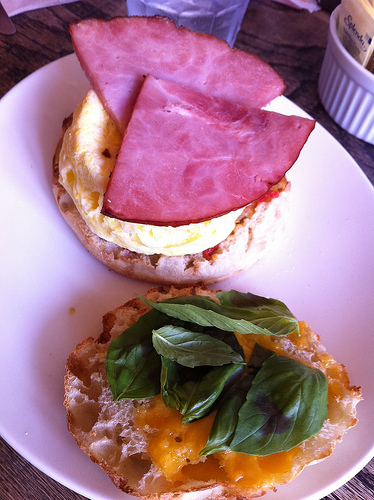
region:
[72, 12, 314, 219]
ham meat on open faced sandwich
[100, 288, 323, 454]
green leaves on the sandwich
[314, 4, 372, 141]
white container on the table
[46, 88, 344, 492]
biscuit cut in half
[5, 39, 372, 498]
white plate on the table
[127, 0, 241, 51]
drinking glass on the table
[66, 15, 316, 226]
Canadian style bacon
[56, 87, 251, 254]
scrambled egg folded over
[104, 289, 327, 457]
several leaves of spinach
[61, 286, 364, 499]
top half of cut English muffin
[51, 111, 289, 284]
bottom half of cut English muffin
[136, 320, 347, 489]
melted cheddar cheese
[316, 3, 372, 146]
white ceramic bowl holding sugar packets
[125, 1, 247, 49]
glass of ice water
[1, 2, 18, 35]
stainless steel table knife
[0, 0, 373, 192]
laminate wood topped table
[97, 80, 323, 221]
triangular slice of red ham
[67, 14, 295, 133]
triangular slice of pink ham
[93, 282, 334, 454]
fresh whole green basil leaves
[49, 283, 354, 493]
toasted slice of English muffin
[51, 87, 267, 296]
toasted slice of English muffin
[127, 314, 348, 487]
melted cheddar cheese on muffin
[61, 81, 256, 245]
yellow egg round on muffin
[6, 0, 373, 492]
wooden table under sandwich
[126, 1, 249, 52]
clear drinking glass with water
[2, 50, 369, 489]
oval white ceramic plate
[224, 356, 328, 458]
green leaf on sandwich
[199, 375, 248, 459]
green leaf on sandwich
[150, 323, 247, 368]
green leaf on sandwich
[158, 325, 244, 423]
green leaf on sandwich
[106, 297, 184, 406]
green leaf on sandwich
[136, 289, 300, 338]
green leaf on sandwich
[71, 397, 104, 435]
whole in a bagel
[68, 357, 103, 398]
whole in a bagel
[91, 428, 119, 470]
whole in a bagel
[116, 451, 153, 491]
whole in a bagel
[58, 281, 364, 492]
Half an english muffin with cheese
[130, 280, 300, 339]
A leaf on an english muffin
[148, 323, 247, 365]
A leaf on an english muffin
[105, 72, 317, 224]
A sliced piece of ham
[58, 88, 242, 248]
Egg on an english muffin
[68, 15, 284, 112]
A slice of ham on an egg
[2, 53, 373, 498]
A white plate with english muffins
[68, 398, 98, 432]
A hole on an english muffin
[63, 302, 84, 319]
A spot of food on a plate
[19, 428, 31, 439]
A crumb on a plate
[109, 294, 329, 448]
spinach leaves on muffin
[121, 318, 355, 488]
orange jam on muffin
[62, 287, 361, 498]
half english muffin on plate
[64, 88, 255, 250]
cooked egg on muffin